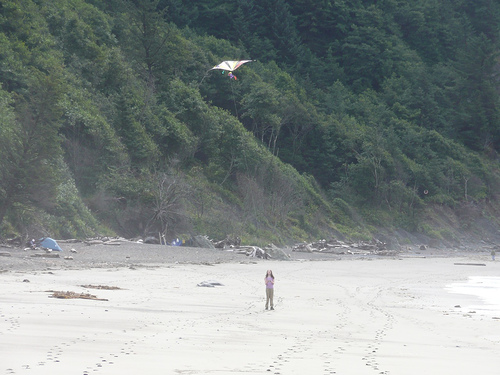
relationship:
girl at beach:
[258, 257, 283, 319] [124, 234, 409, 342]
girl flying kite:
[258, 257, 283, 319] [198, 46, 267, 104]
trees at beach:
[93, 38, 443, 273] [124, 234, 409, 342]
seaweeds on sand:
[38, 282, 130, 313] [110, 289, 223, 348]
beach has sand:
[124, 234, 409, 342] [110, 289, 223, 348]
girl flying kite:
[262, 266, 277, 312] [210, 60, 254, 77]